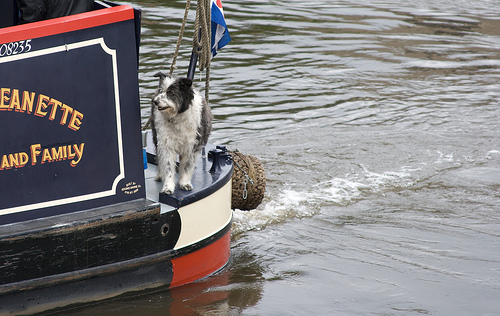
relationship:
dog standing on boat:
[150, 69, 213, 195] [0, 8, 237, 311]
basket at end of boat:
[169, 145, 288, 224] [0, 8, 237, 311]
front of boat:
[161, 155, 252, 303] [0, 8, 237, 311]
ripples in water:
[235, 118, 495, 240] [185, 0, 491, 302]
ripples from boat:
[235, 118, 495, 240] [0, 8, 237, 311]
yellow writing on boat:
[1, 79, 91, 208] [0, 8, 237, 311]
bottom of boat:
[171, 218, 237, 294] [0, 8, 237, 311]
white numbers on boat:
[1, 35, 44, 62] [0, 8, 237, 311]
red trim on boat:
[0, 8, 149, 38] [0, 1, 267, 313]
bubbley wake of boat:
[237, 133, 496, 244] [0, 8, 237, 311]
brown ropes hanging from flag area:
[161, 2, 218, 65] [183, 0, 223, 70]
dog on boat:
[152, 69, 212, 197] [0, 1, 267, 313]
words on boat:
[0, 85, 86, 166] [0, 1, 267, 313]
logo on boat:
[120, 179, 143, 193] [0, 1, 267, 313]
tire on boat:
[232, 151, 266, 209] [0, 1, 267, 313]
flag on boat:
[190, 2, 234, 78] [0, 1, 267, 313]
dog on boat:
[152, 69, 212, 197] [152, 70, 209, 197]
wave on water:
[229, 147, 499, 236] [74, 3, 497, 310]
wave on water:
[229, 144, 493, 236] [74, 3, 497, 310]